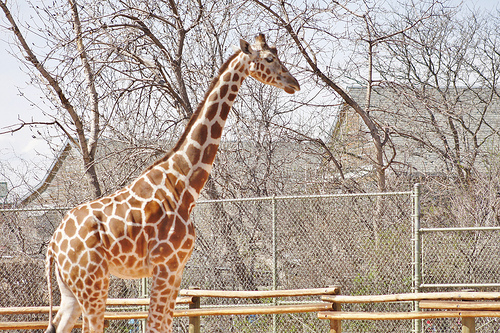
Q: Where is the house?
A: Background.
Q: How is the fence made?
A: Of wood.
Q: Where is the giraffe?
A: Inside fence.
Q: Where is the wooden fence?
A: Behind giraffe.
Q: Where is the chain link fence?
A: Behind the wooden one.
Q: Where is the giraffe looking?
A: Left.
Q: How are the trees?
A: Bare.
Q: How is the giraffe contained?
A: Metal and wooden fences.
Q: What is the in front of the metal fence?
A: A wooden fence.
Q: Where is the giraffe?
A: Zoo.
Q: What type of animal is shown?
A: Giraffe.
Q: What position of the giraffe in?
A: Standing.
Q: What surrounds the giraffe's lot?
A: Fence.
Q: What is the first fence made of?
A: Wood.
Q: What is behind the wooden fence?
A: Metal fence.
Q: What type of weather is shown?
A: Overcast.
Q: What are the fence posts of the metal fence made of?
A: Metal.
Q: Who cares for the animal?
A: A zoo worker.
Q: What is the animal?
A: A giraffe.